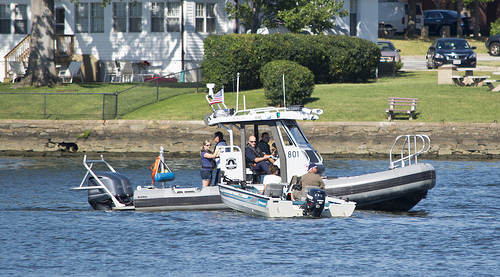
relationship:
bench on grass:
[390, 98, 417, 123] [140, 60, 495, 120]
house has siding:
[0, 0, 377, 83] [111, 36, 183, 60]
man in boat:
[243, 136, 282, 177] [212, 101, 354, 219]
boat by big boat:
[216, 179, 357, 219] [87, 108, 436, 212]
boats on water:
[90, 108, 447, 223] [4, 151, 499, 276]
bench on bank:
[390, 98, 417, 123] [131, 90, 499, 154]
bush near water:
[263, 62, 315, 106] [4, 151, 499, 276]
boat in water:
[216, 179, 357, 219] [4, 151, 499, 276]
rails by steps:
[0, 34, 76, 76] [19, 54, 33, 77]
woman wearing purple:
[201, 139, 213, 187] [202, 144, 218, 171]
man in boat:
[294, 163, 327, 204] [216, 179, 357, 219]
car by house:
[378, 38, 401, 71] [0, 0, 377, 83]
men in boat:
[247, 129, 282, 173] [87, 108, 436, 212]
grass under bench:
[140, 60, 495, 120] [390, 98, 417, 123]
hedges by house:
[206, 35, 381, 86] [0, 0, 377, 83]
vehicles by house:
[378, 7, 499, 76] [0, 0, 377, 83]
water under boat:
[4, 151, 499, 276] [212, 101, 354, 219]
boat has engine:
[212, 101, 354, 219] [297, 186, 332, 214]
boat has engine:
[87, 108, 436, 212] [87, 156, 131, 213]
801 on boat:
[285, 146, 305, 163] [212, 101, 354, 219]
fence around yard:
[0, 66, 208, 122] [0, 55, 203, 118]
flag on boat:
[205, 87, 229, 109] [212, 101, 354, 219]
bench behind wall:
[390, 98, 417, 123] [0, 117, 499, 157]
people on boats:
[196, 129, 325, 197] [90, 108, 447, 223]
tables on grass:
[459, 59, 499, 90] [140, 60, 495, 120]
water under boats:
[4, 151, 499, 276] [90, 108, 447, 223]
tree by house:
[232, 1, 333, 28] [0, 0, 377, 83]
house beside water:
[0, 0, 377, 83] [4, 151, 499, 276]